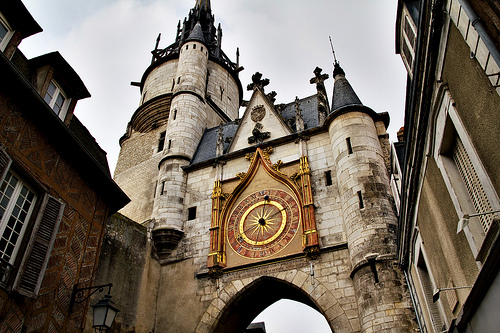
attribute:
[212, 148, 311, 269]
clock — large, brown, gold, red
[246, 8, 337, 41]
sky — light, gray, clear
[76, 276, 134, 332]
lamp — oil, old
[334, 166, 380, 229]
bricks — large, gray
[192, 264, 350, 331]
entryway — arched, tall, large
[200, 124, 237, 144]
roof — black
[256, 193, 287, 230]
hands — black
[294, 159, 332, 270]
edging — gold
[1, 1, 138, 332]
building — stoley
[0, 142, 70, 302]
window — white, open, tall